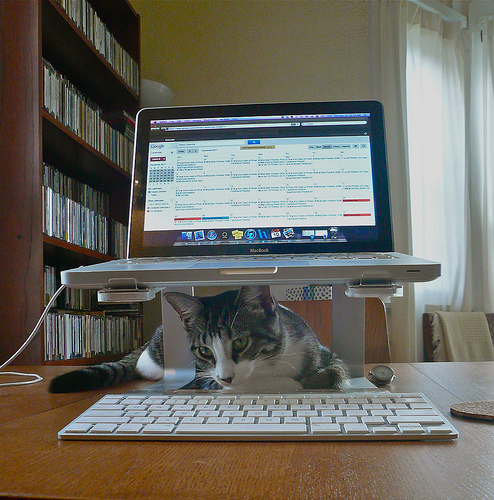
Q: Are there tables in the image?
A: Yes, there is a table.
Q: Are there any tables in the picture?
A: Yes, there is a table.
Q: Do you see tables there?
A: Yes, there is a table.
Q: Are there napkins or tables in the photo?
A: Yes, there is a table.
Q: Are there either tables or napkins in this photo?
A: Yes, there is a table.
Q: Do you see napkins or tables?
A: Yes, there is a table.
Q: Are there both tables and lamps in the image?
A: Yes, there are both a table and a lamp.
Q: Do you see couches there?
A: No, there are no couches.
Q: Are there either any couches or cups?
A: No, there are no couches or cups.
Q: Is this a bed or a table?
A: This is a table.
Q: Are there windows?
A: Yes, there are windows.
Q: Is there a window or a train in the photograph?
A: Yes, there are windows.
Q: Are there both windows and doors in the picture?
A: No, there are windows but no doors.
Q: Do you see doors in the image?
A: No, there are no doors.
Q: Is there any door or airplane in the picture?
A: No, there are no doors or airplanes.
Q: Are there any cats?
A: Yes, there is a cat.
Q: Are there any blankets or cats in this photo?
A: Yes, there is a cat.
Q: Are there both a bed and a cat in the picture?
A: No, there is a cat but no beds.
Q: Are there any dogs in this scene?
A: No, there are no dogs.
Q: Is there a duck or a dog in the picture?
A: No, there are no dogs or ducks.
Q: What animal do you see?
A: The animal is a cat.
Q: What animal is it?
A: The animal is a cat.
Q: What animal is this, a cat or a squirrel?
A: This is a cat.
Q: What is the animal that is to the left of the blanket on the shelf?
A: The animal is a cat.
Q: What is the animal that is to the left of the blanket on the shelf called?
A: The animal is a cat.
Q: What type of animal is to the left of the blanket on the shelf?
A: The animal is a cat.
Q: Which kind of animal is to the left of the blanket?
A: The animal is a cat.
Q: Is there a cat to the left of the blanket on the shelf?
A: Yes, there is a cat to the left of the blanket.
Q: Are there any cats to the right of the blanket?
A: No, the cat is to the left of the blanket.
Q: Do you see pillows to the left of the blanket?
A: No, there is a cat to the left of the blanket.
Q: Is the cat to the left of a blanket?
A: Yes, the cat is to the left of a blanket.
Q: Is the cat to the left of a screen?
A: No, the cat is to the left of a blanket.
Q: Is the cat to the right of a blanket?
A: No, the cat is to the left of a blanket.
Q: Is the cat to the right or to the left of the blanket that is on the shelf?
A: The cat is to the left of the blanket.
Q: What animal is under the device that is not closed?
A: The cat is under the laptop.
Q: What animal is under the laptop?
A: The cat is under the laptop.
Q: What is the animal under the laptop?
A: The animal is a cat.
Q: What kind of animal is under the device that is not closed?
A: The animal is a cat.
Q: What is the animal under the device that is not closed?
A: The animal is a cat.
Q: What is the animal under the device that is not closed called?
A: The animal is a cat.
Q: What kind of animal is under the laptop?
A: The animal is a cat.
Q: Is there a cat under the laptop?
A: Yes, there is a cat under the laptop.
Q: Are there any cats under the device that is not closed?
A: Yes, there is a cat under the laptop.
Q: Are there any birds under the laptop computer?
A: No, there is a cat under the laptop computer.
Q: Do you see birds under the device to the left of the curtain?
A: No, there is a cat under the laptop computer.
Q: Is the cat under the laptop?
A: Yes, the cat is under the laptop.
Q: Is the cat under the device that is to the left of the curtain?
A: Yes, the cat is under the laptop.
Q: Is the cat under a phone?
A: No, the cat is under the laptop.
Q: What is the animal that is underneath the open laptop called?
A: The animal is a cat.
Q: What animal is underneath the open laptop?
A: The animal is a cat.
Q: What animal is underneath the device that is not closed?
A: The animal is a cat.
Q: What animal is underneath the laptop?
A: The animal is a cat.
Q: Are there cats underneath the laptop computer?
A: Yes, there is a cat underneath the laptop computer.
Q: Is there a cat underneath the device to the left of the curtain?
A: Yes, there is a cat underneath the laptop computer.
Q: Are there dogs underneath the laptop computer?
A: No, there is a cat underneath the laptop computer.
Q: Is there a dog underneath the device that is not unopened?
A: No, there is a cat underneath the laptop computer.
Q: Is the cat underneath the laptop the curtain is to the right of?
A: Yes, the cat is underneath the laptop computer.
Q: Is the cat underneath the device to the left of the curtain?
A: Yes, the cat is underneath the laptop computer.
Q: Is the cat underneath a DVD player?
A: No, the cat is underneath the laptop computer.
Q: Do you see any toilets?
A: No, there are no toilets.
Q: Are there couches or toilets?
A: No, there are no toilets or couches.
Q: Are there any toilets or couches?
A: No, there are no toilets or couches.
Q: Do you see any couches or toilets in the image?
A: No, there are no toilets or couches.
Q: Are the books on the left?
A: Yes, the books are on the left of the image.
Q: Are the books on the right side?
A: No, the books are on the left of the image.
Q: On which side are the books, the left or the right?
A: The books are on the left of the image.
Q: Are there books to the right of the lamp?
A: No, the books are to the left of the lamp.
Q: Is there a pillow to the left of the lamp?
A: No, there are books to the left of the lamp.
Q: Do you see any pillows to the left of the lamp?
A: No, there are books to the left of the lamp.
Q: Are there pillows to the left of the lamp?
A: No, there are books to the left of the lamp.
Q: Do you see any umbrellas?
A: No, there are no umbrellas.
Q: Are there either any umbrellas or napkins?
A: No, there are no umbrellas or napkins.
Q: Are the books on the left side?
A: Yes, the books are on the left of the image.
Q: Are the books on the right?
A: No, the books are on the left of the image.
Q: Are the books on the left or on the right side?
A: The books are on the left of the image.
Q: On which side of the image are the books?
A: The books are on the left of the image.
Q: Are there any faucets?
A: No, there are no faucets.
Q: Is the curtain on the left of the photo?
A: No, the curtain is on the right of the image.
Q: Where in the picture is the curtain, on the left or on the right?
A: The curtain is on the right of the image.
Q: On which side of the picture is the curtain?
A: The curtain is on the right of the image.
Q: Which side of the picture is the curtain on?
A: The curtain is on the right of the image.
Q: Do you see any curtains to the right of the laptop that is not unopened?
A: Yes, there is a curtain to the right of the laptop.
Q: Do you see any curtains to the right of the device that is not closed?
A: Yes, there is a curtain to the right of the laptop.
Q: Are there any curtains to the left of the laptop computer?
A: No, the curtain is to the right of the laptop computer.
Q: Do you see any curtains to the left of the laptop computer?
A: No, the curtain is to the right of the laptop computer.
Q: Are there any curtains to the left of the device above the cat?
A: No, the curtain is to the right of the laptop computer.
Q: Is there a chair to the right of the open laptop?
A: No, there is a curtain to the right of the laptop computer.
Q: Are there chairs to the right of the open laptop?
A: No, there is a curtain to the right of the laptop computer.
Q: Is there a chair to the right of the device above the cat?
A: No, there is a curtain to the right of the laptop computer.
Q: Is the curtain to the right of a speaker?
A: No, the curtain is to the right of the laptop.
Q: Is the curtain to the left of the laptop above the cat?
A: No, the curtain is to the right of the laptop.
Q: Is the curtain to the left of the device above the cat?
A: No, the curtain is to the right of the laptop.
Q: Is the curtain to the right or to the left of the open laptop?
A: The curtain is to the right of the laptop computer.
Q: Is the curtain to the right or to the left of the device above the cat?
A: The curtain is to the right of the laptop computer.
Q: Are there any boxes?
A: No, there are no boxes.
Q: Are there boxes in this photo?
A: No, there are no boxes.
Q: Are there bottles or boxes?
A: No, there are no boxes or bottles.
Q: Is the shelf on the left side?
A: Yes, the shelf is on the left of the image.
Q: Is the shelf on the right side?
A: No, the shelf is on the left of the image.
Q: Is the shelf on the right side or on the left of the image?
A: The shelf is on the left of the image.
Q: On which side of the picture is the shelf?
A: The shelf is on the left of the image.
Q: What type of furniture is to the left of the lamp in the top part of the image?
A: The piece of furniture is a shelf.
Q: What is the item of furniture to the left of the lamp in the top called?
A: The piece of furniture is a shelf.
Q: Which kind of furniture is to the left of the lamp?
A: The piece of furniture is a shelf.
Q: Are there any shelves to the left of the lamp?
A: Yes, there is a shelf to the left of the lamp.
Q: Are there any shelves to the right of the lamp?
A: No, the shelf is to the left of the lamp.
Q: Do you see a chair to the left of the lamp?
A: No, there is a shelf to the left of the lamp.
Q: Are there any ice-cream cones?
A: No, there are no ice-cream cones.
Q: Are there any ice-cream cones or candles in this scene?
A: No, there are no ice-cream cones or candles.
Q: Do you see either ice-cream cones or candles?
A: No, there are no ice-cream cones or candles.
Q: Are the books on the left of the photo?
A: Yes, the books are on the left of the image.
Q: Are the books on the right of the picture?
A: No, the books are on the left of the image.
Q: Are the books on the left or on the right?
A: The books are on the left of the image.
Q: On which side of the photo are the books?
A: The books are on the left of the image.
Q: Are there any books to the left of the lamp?
A: Yes, there are books to the left of the lamp.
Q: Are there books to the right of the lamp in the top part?
A: No, the books are to the left of the lamp.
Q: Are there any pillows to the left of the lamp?
A: No, there are books to the left of the lamp.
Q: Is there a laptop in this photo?
A: Yes, there is a laptop.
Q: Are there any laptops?
A: Yes, there is a laptop.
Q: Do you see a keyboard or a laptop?
A: Yes, there is a laptop.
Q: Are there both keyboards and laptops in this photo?
A: Yes, there are both a laptop and a keyboard.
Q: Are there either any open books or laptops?
A: Yes, there is an open laptop.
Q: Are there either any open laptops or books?
A: Yes, there is an open laptop.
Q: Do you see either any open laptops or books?
A: Yes, there is an open laptop.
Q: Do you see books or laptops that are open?
A: Yes, the laptop is open.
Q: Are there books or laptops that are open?
A: Yes, the laptop is open.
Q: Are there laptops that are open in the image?
A: Yes, there is an open laptop.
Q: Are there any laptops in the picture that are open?
A: Yes, there is a laptop that is open.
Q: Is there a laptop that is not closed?
A: Yes, there is a open laptop.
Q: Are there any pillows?
A: No, there are no pillows.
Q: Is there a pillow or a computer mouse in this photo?
A: No, there are no pillows or computer mice.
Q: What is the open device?
A: The device is a laptop.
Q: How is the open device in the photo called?
A: The device is a laptop.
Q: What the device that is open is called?
A: The device is a laptop.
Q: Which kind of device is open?
A: The device is a laptop.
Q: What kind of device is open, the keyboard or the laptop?
A: The laptop is open.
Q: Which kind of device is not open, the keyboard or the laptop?
A: The keyboard is not open.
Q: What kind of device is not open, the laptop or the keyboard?
A: The keyboard is not open.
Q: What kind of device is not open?
A: The device is a keyboard.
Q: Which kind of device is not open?
A: The device is a keyboard.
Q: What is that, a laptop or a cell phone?
A: That is a laptop.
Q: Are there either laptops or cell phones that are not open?
A: No, there is a laptop but it is open.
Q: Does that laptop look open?
A: Yes, the laptop is open.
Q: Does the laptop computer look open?
A: Yes, the laptop computer is open.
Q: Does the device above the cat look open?
A: Yes, the laptop computer is open.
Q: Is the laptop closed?
A: No, the laptop is open.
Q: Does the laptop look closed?
A: No, the laptop is open.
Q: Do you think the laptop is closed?
A: No, the laptop is open.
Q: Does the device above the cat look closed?
A: No, the laptop is open.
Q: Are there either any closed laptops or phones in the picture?
A: No, there is a laptop but it is open.